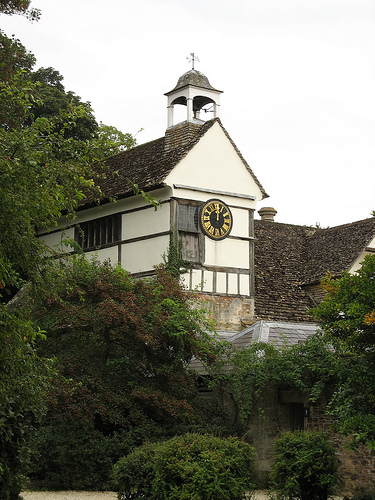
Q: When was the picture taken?
A: Daytime.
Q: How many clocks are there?
A: One.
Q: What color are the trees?
A: Green.